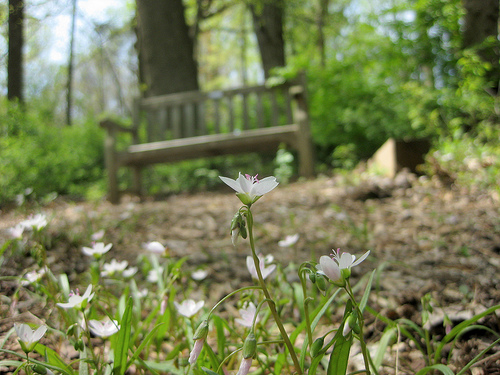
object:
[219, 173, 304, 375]
flower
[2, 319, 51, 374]
flowers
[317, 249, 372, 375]
flower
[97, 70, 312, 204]
bench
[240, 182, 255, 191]
white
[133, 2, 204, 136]
trunk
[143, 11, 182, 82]
brown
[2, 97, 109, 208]
leaves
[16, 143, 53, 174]
green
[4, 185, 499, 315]
ground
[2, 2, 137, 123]
sky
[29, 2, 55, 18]
blue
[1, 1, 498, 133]
woods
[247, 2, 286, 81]
tree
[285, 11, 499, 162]
bushes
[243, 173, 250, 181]
pink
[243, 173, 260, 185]
center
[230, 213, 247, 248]
bud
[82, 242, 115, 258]
opened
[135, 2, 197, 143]
trees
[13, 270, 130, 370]
cluster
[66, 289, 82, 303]
stamen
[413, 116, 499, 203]
weeds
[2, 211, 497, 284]
trail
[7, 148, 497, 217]
grass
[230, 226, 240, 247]
tip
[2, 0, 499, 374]
picture